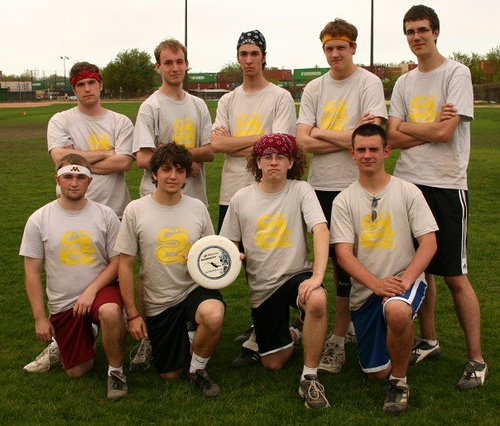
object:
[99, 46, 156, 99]
tree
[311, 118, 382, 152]
arms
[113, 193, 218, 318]
shirt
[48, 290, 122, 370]
shorts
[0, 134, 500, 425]
ground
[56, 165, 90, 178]
headband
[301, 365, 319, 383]
white sock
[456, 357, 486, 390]
shoe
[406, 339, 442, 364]
shoe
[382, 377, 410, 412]
shoe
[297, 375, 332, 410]
shoe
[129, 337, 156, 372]
shoe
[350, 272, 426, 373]
blue shorts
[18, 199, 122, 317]
white t-shirt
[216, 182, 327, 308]
white t-shirt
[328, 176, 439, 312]
white t-shirt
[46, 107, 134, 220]
white t-shirt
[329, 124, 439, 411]
man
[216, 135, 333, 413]
man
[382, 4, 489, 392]
man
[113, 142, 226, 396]
man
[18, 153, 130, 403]
man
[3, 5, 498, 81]
sky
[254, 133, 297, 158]
bandana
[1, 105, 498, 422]
large field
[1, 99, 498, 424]
green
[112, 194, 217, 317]
white t-shirt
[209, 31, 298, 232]
player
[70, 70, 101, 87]
bandana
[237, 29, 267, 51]
bandana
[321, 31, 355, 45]
orange bandanna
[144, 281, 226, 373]
shorts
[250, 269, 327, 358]
shorts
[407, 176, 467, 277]
shorts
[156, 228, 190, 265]
snake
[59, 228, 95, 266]
logo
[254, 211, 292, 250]
logo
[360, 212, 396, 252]
logo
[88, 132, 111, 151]
logo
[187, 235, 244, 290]
frisbe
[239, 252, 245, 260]
hand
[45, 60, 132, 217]
boy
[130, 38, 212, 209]
boy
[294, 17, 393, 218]
boy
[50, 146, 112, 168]
arms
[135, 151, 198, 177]
arms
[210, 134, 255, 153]
arms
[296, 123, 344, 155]
arms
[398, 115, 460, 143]
arms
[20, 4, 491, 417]
group